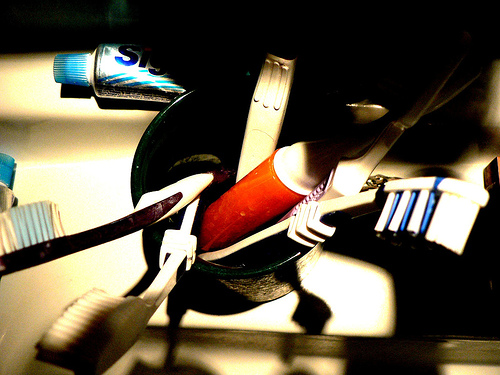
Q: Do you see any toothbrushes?
A: Yes, there is a toothbrush.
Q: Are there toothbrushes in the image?
A: Yes, there is a toothbrush.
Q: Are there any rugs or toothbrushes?
A: Yes, there is a toothbrush.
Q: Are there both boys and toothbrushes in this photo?
A: No, there is a toothbrush but no boys.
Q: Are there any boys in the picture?
A: No, there are no boys.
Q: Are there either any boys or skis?
A: No, there are no boys or skis.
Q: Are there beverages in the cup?
A: No, there is a toothbrush in the cup.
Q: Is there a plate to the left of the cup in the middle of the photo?
A: No, there is a toothbrush to the left of the cup.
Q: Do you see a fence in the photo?
A: No, there are no fences.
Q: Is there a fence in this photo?
A: No, there are no fences.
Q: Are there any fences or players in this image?
A: No, there are no fences or players.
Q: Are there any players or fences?
A: No, there are no fences or players.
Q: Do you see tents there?
A: No, there are no tents.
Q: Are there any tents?
A: No, there are no tents.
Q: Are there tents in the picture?
A: No, there are no tents.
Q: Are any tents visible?
A: No, there are no tents.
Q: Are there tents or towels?
A: No, there are no tents or towels.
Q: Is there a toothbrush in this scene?
A: Yes, there is a toothbrush.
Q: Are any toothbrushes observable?
A: Yes, there is a toothbrush.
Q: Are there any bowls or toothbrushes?
A: Yes, there is a toothbrush.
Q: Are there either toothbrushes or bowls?
A: Yes, there is a toothbrush.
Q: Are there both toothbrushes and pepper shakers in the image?
A: No, there is a toothbrush but no pepper shakers.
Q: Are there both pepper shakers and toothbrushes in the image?
A: No, there is a toothbrush but no pepper shakers.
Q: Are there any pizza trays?
A: No, there are no pizza trays.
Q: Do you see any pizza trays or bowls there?
A: No, there are no pizza trays or bowls.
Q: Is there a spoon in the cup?
A: No, there is a toothbrush in the cup.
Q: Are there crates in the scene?
A: No, there are no crates.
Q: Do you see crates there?
A: No, there are no crates.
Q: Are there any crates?
A: No, there are no crates.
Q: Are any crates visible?
A: No, there are no crates.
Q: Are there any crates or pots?
A: No, there are no crates or pots.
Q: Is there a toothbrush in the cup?
A: Yes, there are toothbrushes in the cup.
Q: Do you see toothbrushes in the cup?
A: Yes, there are toothbrushes in the cup.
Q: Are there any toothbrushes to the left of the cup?
A: Yes, there are toothbrushes to the left of the cup.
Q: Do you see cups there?
A: Yes, there is a cup.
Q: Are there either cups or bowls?
A: Yes, there is a cup.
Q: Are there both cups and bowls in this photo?
A: No, there is a cup but no bowls.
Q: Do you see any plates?
A: No, there are no plates.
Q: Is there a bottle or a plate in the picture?
A: No, there are no plates or bottles.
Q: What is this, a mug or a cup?
A: This is a cup.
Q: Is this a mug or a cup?
A: This is a cup.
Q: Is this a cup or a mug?
A: This is a cup.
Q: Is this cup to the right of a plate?
A: No, the cup is to the right of a toothbrush.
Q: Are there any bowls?
A: No, there are no bowls.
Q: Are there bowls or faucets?
A: No, there are no bowls or faucets.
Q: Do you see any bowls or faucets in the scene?
A: No, there are no bowls or faucets.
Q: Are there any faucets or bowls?
A: No, there are no bowls or faucets.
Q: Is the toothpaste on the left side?
A: Yes, the toothpaste is on the left of the image.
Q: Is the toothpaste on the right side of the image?
A: No, the toothpaste is on the left of the image.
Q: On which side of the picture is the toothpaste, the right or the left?
A: The toothpaste is on the left of the image.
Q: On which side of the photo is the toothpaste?
A: The toothpaste is on the left of the image.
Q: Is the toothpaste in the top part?
A: Yes, the toothpaste is in the top of the image.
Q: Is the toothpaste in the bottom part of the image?
A: No, the toothpaste is in the top of the image.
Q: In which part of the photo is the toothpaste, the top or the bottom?
A: The toothpaste is in the top of the image.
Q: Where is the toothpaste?
A: The toothpaste is at the sink.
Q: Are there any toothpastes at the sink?
A: Yes, there is a toothpaste at the sink.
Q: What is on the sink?
A: The toothpaste is on the sink.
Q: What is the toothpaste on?
A: The toothpaste is on the sink.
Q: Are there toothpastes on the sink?
A: Yes, there is a toothpaste on the sink.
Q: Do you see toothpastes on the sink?
A: Yes, there is a toothpaste on the sink.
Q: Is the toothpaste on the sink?
A: Yes, the toothpaste is on the sink.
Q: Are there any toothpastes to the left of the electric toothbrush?
A: Yes, there is a toothpaste to the left of the electric toothbrush.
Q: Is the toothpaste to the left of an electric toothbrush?
A: Yes, the toothpaste is to the left of an electric toothbrush.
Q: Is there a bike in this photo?
A: No, there are no bikes.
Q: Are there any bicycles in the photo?
A: No, there are no bicycles.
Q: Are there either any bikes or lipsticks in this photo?
A: No, there are no bikes or lipsticks.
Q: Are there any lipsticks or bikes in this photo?
A: No, there are no bikes or lipsticks.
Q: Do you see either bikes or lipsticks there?
A: No, there are no bikes or lipsticks.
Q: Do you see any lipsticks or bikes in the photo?
A: No, there are no bikes or lipsticks.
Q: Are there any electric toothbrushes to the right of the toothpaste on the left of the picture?
A: Yes, there is an electric toothbrush to the right of the toothpaste.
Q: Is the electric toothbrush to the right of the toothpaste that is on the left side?
A: Yes, the electric toothbrush is to the right of the toothpaste.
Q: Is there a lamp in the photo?
A: No, there are no lamps.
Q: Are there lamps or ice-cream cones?
A: No, there are no lamps or ice-cream cones.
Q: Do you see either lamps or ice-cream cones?
A: No, there are no lamps or ice-cream cones.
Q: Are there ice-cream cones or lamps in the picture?
A: No, there are no lamps or ice-cream cones.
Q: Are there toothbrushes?
A: Yes, there is a toothbrush.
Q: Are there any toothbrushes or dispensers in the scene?
A: Yes, there is a toothbrush.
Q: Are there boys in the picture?
A: No, there are no boys.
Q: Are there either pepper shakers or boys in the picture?
A: No, there are no boys or pepper shakers.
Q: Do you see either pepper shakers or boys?
A: No, there are no boys or pepper shakers.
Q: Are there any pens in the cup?
A: No, there is a toothbrush in the cup.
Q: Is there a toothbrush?
A: Yes, there is a toothbrush.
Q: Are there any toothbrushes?
A: Yes, there is a toothbrush.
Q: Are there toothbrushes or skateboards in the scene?
A: Yes, there is a toothbrush.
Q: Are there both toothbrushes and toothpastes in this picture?
A: Yes, there are both a toothbrush and a toothpaste.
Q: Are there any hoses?
A: No, there are no hoses.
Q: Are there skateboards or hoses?
A: No, there are no hoses or skateboards.